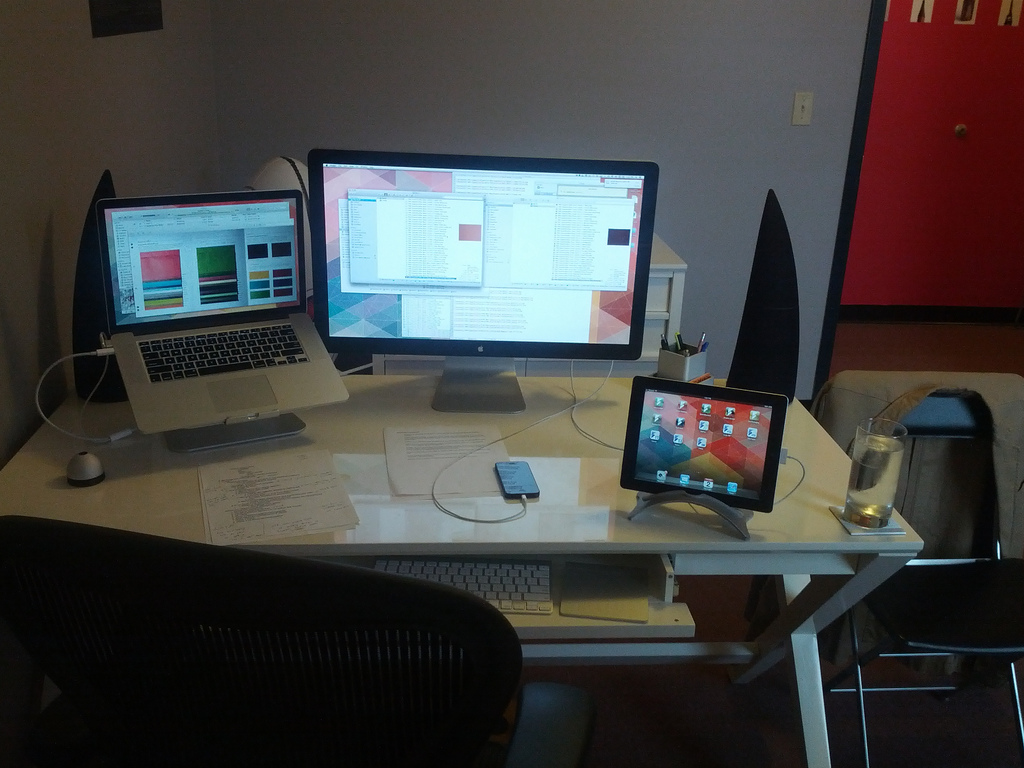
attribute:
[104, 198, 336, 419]
laptop — here, propped, small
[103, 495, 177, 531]
desk — here, brown, beige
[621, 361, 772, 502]
tablet — here, black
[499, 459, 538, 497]
phone — charging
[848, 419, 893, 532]
glass — clear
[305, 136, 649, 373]
monitor — large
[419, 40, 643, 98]
wall — blue, red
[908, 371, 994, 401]
jacket — beige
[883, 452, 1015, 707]
chair — black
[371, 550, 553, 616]
keyboard — here, white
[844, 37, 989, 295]
door — red